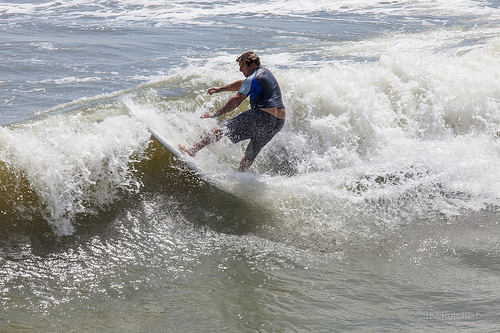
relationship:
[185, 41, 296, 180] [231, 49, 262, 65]
man has hair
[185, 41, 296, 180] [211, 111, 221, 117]
man wearing bracelet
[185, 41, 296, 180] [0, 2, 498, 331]
man in water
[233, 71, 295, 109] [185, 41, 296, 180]
shirt on man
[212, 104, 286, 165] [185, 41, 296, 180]
shorts on man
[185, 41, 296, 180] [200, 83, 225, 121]
man has hands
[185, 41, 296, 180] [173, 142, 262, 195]
man has feet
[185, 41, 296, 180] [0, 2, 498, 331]
man surfing in water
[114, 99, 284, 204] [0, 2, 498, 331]
board over water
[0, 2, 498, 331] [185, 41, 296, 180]
water behind man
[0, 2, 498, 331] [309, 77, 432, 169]
water white and foaming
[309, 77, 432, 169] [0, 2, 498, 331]
foaming in water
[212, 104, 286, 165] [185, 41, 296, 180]
shorts are on man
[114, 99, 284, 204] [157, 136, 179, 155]
board under man white